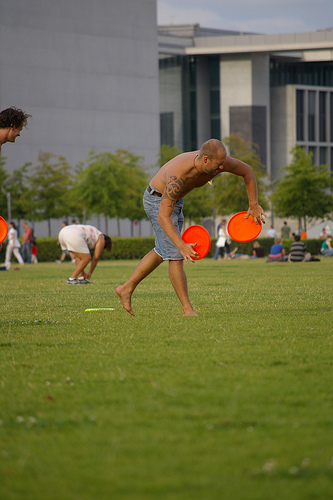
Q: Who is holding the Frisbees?
A: The man on the right.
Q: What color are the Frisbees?
A: Orange.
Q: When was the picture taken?
A: Daytime.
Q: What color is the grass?
A: Green.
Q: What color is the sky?
A: Blue.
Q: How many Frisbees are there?
A: Two.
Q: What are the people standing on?
A: Grass.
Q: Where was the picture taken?
A: In a grassy yard at a home.